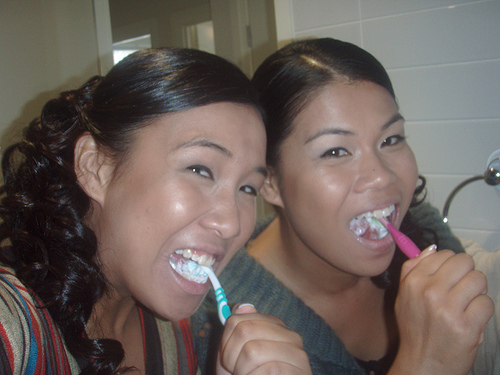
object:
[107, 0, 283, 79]
door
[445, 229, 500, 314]
towel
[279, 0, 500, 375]
wall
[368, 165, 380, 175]
mole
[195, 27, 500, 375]
girl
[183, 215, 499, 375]
sweater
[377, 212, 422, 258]
brush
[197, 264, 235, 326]
tooth brush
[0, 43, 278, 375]
friend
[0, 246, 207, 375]
shirt